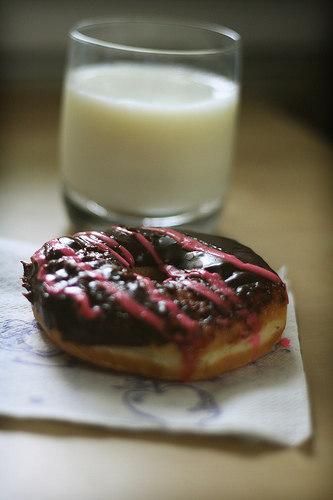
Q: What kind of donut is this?
A: Chocolate-frosted.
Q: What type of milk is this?
A: White milk.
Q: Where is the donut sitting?
A: On the napkin.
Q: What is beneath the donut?
A: A white napkin.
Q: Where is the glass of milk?
A: Behind the donut.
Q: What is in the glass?
A: Milk.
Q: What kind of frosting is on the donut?
A: Chocolate.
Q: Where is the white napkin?
A: On the table.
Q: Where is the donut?
A: On the napkin.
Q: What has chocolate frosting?
A: The donut.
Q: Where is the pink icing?
A: On the donut.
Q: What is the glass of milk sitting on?
A: The table.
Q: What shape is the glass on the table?
A: Round.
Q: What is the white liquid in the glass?
A: Milk.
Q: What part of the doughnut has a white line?
A: The side.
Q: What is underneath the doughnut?
A: A napkin.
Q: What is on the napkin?
A: A donut.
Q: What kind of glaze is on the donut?
A: Chocolate.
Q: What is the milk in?
A: A small drinking glass.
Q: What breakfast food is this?
A: Doughnut.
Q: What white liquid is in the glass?
A: Milk.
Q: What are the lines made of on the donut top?
A: Icing.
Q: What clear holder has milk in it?
A: Glass.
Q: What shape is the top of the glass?
A: Circle.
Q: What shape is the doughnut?
A: Circle.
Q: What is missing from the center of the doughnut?
A: Hole.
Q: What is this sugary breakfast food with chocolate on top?
A: Donut.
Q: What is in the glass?
A: Milk.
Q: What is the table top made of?
A: Wood.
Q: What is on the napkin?
A: A donut.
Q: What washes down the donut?
A: A glass of milk.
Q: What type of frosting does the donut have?
A: Chocolate with pink stripes.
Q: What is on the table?
A: Milk and a donut.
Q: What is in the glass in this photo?
A: Milk.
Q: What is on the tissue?
A: A doughnut.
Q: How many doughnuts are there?
A: 1.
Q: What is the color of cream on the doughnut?
A: Pink.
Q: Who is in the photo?
A: No one.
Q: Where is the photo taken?
A: At the table.